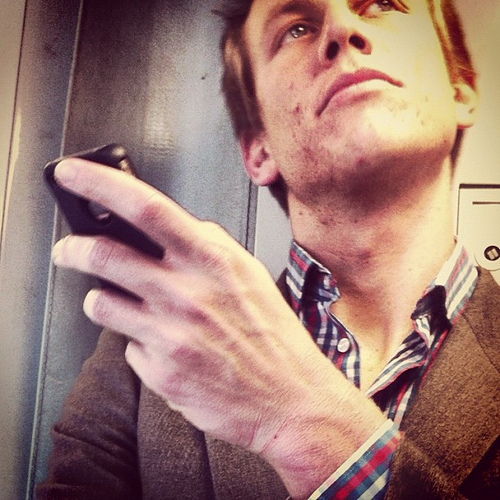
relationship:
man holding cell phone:
[235, 6, 454, 236] [30, 127, 201, 297]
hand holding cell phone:
[88, 178, 307, 444] [6, 113, 147, 289]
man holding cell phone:
[23, 0, 500, 498] [41, 142, 167, 296]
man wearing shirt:
[23, 0, 500, 498] [265, 233, 460, 454]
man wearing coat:
[244, 7, 449, 183] [68, 280, 428, 497]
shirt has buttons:
[278, 250, 489, 398] [326, 325, 369, 369]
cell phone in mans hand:
[41, 142, 167, 296] [115, 155, 305, 435]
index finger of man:
[20, 137, 210, 267] [231, 17, 431, 200]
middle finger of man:
[42, 204, 202, 304] [249, 40, 425, 180]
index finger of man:
[20, 137, 210, 267] [244, 16, 437, 215]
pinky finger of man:
[101, 311, 162, 399] [251, 9, 427, 208]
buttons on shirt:
[300, 259, 352, 355] [279, 234, 465, 422]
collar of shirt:
[259, 231, 469, 331] [284, 242, 438, 492]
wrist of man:
[239, 367, 402, 487] [232, 16, 448, 207]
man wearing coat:
[23, 0, 500, 498] [35, 268, 500, 498]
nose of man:
[312, 11, 393, 69] [23, 0, 500, 498]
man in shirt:
[23, 0, 500, 498] [259, 236, 440, 460]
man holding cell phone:
[23, 0, 500, 498] [30, 133, 183, 294]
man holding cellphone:
[23, 0, 500, 498] [40, 140, 174, 294]